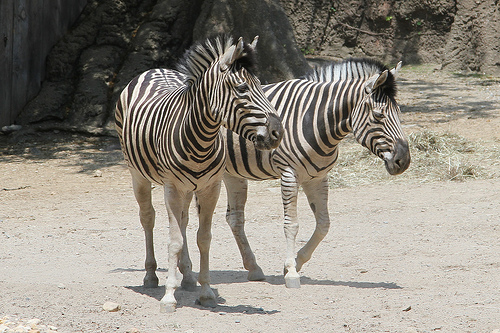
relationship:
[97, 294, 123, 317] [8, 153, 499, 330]
rock on dirt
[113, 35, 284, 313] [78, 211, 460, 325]
zebra on dirt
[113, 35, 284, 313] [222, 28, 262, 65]
zebra has ear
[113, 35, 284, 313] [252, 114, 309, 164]
zebra has nose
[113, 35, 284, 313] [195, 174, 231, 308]
zebra has leg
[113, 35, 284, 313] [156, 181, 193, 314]
zebra has leg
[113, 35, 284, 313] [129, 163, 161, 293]
zebra has leg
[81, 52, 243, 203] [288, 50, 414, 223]
zebra beside zebra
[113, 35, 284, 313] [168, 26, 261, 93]
zebra has mane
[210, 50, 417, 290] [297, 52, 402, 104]
zebra has mane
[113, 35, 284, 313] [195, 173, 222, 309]
zebra has leg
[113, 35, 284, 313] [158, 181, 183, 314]
zebra has leg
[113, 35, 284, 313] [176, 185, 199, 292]
zebra has leg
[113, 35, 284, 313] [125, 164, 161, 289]
zebra has leg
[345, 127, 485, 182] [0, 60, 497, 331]
bush on ground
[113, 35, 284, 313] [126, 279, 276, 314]
zebra has shadow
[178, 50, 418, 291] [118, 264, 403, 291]
zebra has shadow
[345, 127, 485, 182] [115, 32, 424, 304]
bush for zebras